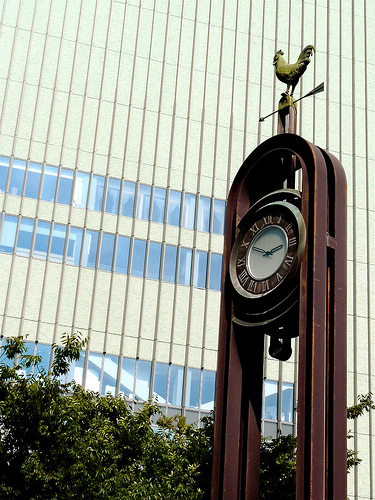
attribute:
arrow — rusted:
[254, 73, 337, 128]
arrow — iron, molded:
[240, 79, 330, 124]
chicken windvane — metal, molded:
[259, 43, 324, 127]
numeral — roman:
[242, 184, 287, 239]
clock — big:
[224, 193, 308, 308]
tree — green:
[10, 388, 214, 493]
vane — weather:
[256, 84, 324, 124]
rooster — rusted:
[269, 41, 316, 96]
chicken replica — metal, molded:
[266, 43, 317, 100]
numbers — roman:
[237, 253, 247, 282]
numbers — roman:
[255, 216, 289, 229]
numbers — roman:
[285, 231, 298, 267]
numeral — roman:
[240, 243, 250, 250]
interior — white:
[247, 249, 274, 274]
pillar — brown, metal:
[295, 306, 346, 498]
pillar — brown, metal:
[211, 320, 266, 498]